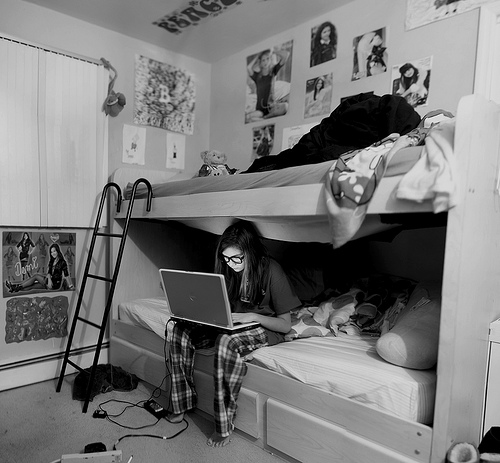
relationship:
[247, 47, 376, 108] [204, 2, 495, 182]
posters on wall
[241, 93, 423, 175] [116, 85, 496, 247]
cloth is on bed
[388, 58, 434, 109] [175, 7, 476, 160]
poster is on wall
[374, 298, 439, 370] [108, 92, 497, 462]
pillow is on bed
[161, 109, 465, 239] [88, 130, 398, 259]
blankets is on bed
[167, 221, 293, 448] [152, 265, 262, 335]
girl using laptop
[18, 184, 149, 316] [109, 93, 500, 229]
ladder leads to bed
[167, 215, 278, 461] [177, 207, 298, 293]
girl has hair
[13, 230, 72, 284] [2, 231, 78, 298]
women on pictures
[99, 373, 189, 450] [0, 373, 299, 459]
cord on floor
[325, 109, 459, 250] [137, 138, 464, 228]
blankets on bed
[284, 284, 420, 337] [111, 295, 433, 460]
blankets on bed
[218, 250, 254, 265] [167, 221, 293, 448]
eyeglasses on girl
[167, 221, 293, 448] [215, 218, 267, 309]
girl has hair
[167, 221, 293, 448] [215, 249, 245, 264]
girl wearing glasses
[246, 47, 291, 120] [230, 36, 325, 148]
woman on a poster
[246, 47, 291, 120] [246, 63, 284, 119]
woman wearing a leotard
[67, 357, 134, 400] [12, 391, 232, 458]
towel on floor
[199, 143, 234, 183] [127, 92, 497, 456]
teddy bear perched on bunk bed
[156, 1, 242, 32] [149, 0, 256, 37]
word on poster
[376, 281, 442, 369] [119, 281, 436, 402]
pillow laying on bed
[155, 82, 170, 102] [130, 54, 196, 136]
letter b laying on poster